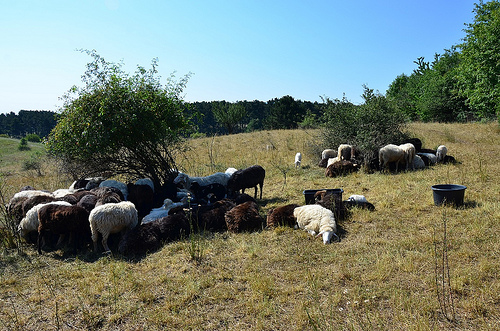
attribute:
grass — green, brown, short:
[17, 257, 407, 329]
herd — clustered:
[6, 156, 274, 250]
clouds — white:
[1, 0, 499, 115]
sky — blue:
[0, 0, 498, 116]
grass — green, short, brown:
[190, 259, 385, 323]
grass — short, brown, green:
[1, 117, 497, 327]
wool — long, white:
[86, 200, 135, 240]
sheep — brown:
[226, 199, 264, 231]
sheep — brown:
[267, 202, 299, 224]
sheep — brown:
[313, 187, 349, 217]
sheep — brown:
[37, 202, 91, 256]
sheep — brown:
[325, 158, 353, 175]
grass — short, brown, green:
[1, 250, 431, 330]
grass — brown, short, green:
[199, 268, 471, 310]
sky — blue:
[253, 14, 370, 84]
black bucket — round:
[427, 180, 469, 206]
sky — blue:
[308, 13, 363, 42]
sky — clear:
[154, 1, 382, 71]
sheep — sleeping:
[288, 197, 339, 247]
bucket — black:
[429, 180, 468, 211]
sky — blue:
[2, 0, 482, 101]